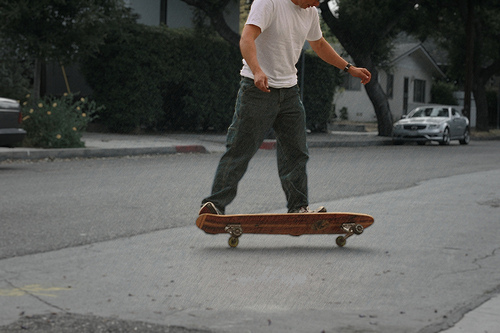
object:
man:
[198, 0, 372, 216]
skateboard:
[194, 212, 375, 249]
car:
[389, 105, 472, 145]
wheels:
[231, 225, 243, 237]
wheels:
[353, 224, 364, 235]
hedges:
[85, 23, 338, 134]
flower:
[79, 110, 87, 118]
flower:
[55, 134, 63, 140]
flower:
[79, 97, 85, 104]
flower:
[46, 112, 52, 114]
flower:
[36, 102, 45, 108]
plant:
[18, 86, 104, 147]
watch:
[343, 63, 354, 74]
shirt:
[237, 0, 322, 89]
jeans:
[202, 75, 311, 211]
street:
[0, 138, 498, 331]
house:
[326, 42, 446, 123]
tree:
[320, 0, 439, 137]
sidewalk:
[0, 127, 389, 158]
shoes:
[196, 201, 223, 214]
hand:
[350, 67, 372, 84]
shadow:
[196, 244, 377, 254]